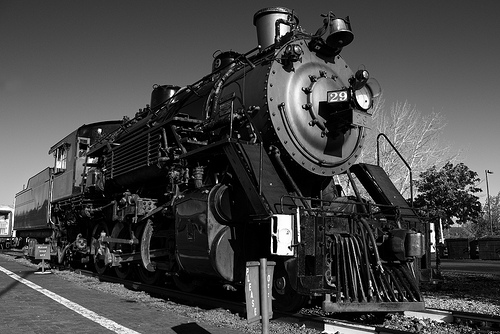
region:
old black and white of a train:
[4, 5, 493, 325]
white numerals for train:
[326, 84, 349, 103]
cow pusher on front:
[305, 218, 439, 314]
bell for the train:
[322, 12, 355, 52]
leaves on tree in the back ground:
[417, 163, 484, 227]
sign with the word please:
[241, 262, 281, 332]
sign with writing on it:
[32, 243, 52, 268]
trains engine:
[85, 3, 428, 316]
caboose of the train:
[16, 163, 57, 244]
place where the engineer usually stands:
[52, 130, 82, 208]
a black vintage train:
[67, 97, 456, 306]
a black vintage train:
[131, 45, 340, 235]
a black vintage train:
[62, 67, 203, 240]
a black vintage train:
[119, 186, 410, 319]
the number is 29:
[314, 88, 364, 108]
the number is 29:
[318, 76, 367, 121]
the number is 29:
[303, 86, 366, 131]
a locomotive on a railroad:
[1, 3, 455, 332]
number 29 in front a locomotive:
[273, 27, 381, 158]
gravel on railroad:
[296, 290, 491, 330]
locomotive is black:
[10, 5, 440, 311]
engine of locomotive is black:
[81, 4, 433, 314]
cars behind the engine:
[6, 102, 91, 258]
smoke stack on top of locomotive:
[244, 0, 302, 57]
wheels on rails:
[56, 255, 148, 289]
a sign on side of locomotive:
[30, 237, 58, 279]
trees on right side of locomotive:
[401, 116, 494, 238]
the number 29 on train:
[324, 88, 352, 104]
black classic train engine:
[43, 0, 437, 330]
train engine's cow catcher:
[309, 212, 429, 317]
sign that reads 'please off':
[241, 256, 283, 330]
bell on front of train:
[318, 8, 358, 53]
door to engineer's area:
[75, 135, 90, 182]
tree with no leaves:
[332, 91, 464, 211]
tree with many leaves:
[405, 157, 486, 231]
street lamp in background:
[481, 163, 496, 239]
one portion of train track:
[401, 300, 497, 327]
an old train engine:
[37, 5, 482, 330]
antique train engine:
[11, 0, 453, 328]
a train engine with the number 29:
[249, 0, 446, 333]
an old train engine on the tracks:
[32, 0, 459, 332]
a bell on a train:
[320, 8, 383, 63]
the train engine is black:
[36, 1, 416, 326]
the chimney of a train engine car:
[246, 5, 308, 81]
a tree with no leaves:
[368, 90, 458, 194]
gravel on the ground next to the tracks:
[429, 290, 497, 313]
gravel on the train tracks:
[378, 313, 467, 332]